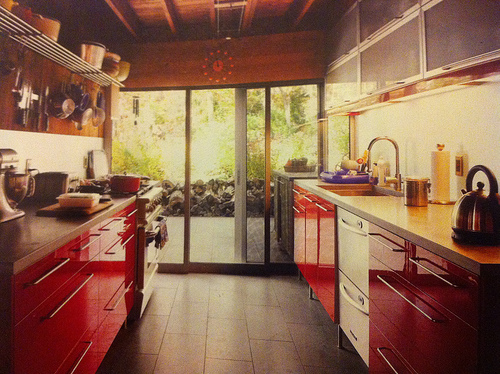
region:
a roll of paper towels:
[427, 140, 454, 206]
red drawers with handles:
[4, 198, 141, 373]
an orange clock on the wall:
[199, 48, 236, 81]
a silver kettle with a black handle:
[450, 163, 499, 243]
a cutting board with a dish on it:
[37, 188, 112, 216]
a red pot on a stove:
[106, 168, 146, 198]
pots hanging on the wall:
[8, 58, 110, 132]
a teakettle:
[439, 153, 499, 248]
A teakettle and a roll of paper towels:
[428, 137, 498, 249]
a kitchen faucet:
[356, 130, 406, 196]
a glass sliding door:
[146, 88, 283, 280]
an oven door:
[130, 170, 176, 328]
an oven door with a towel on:
[131, 174, 178, 328]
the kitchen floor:
[146, 247, 363, 362]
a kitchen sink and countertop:
[326, 183, 398, 220]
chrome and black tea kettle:
[440, 160, 487, 244]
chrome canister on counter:
[400, 163, 435, 211]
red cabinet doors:
[287, 184, 334, 314]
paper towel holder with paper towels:
[427, 135, 450, 213]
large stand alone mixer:
[1, 146, 29, 226]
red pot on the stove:
[109, 164, 149, 194]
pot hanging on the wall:
[50, 86, 76, 122]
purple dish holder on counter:
[317, 148, 365, 182]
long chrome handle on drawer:
[371, 269, 448, 324]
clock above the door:
[188, 43, 245, 85]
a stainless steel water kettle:
[451, 167, 498, 244]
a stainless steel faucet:
[364, 133, 404, 191]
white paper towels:
[430, 142, 451, 204]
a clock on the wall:
[196, 47, 234, 84]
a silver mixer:
[0, 146, 31, 221]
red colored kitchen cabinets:
[368, 220, 489, 372]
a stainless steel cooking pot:
[76, 35, 108, 74]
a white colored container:
[56, 188, 101, 208]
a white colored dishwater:
[336, 203, 366, 363]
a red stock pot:
[107, 169, 144, 195]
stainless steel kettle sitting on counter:
[448, 158, 498, 245]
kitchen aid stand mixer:
[0, 143, 34, 226]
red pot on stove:
[107, 167, 141, 196]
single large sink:
[315, 177, 403, 202]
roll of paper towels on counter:
[429, 137, 456, 209]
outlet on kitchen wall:
[450, 153, 465, 176]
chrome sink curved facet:
[363, 132, 401, 196]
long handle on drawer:
[372, 269, 447, 330]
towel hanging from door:
[153, 217, 170, 250]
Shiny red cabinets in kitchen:
[1, 202, 139, 372]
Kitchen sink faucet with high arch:
[366, 135, 405, 192]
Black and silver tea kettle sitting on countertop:
[451, 165, 499, 247]